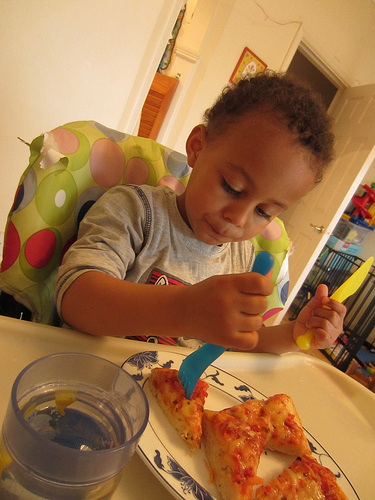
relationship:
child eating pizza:
[51, 70, 347, 355] [146, 364, 347, 498]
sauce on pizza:
[160, 372, 183, 396] [151, 365, 199, 448]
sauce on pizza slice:
[172, 381, 182, 394] [149, 366, 208, 451]